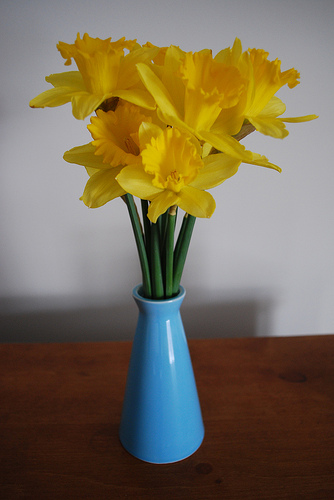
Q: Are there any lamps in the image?
A: No, there are no lamps.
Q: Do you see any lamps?
A: No, there are no lamps.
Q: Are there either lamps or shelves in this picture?
A: No, there are no lamps or shelves.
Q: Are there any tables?
A: Yes, there is a table.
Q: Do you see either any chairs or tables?
A: Yes, there is a table.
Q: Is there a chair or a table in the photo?
A: Yes, there is a table.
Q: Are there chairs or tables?
A: Yes, there is a table.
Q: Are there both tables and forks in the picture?
A: No, there is a table but no forks.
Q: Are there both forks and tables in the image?
A: No, there is a table but no forks.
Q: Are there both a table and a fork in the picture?
A: No, there is a table but no forks.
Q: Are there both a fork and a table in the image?
A: No, there is a table but no forks.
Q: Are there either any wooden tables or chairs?
A: Yes, there is a wood table.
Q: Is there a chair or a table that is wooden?
A: Yes, the table is wooden.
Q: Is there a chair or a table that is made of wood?
A: Yes, the table is made of wood.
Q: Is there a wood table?
A: Yes, there is a table that is made of wood.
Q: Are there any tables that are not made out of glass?
A: Yes, there is a table that is made of wood.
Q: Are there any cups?
A: No, there are no cups.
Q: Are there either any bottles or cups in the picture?
A: No, there are no cups or bottles.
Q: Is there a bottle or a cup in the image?
A: No, there are no cups or bottles.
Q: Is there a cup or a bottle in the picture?
A: No, there are no cups or bottles.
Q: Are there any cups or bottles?
A: No, there are no cups or bottles.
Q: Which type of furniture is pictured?
A: The furniture is a table.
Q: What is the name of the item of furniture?
A: The piece of furniture is a table.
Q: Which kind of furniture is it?
A: The piece of furniture is a table.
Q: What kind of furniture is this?
A: This is a table.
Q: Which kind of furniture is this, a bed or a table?
A: This is a table.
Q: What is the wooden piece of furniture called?
A: The piece of furniture is a table.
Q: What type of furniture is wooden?
A: The furniture is a table.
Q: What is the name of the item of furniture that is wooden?
A: The piece of furniture is a table.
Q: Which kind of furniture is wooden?
A: The furniture is a table.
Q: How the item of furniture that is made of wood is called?
A: The piece of furniture is a table.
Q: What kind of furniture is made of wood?
A: The furniture is a table.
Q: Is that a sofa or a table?
A: That is a table.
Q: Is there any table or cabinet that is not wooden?
A: No, there is a table but it is wooden.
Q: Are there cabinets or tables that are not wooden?
A: No, there is a table but it is wooden.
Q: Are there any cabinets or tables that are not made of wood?
A: No, there is a table but it is made of wood.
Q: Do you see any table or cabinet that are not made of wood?
A: No, there is a table but it is made of wood.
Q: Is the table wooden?
A: Yes, the table is wooden.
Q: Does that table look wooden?
A: Yes, the table is wooden.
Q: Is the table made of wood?
A: Yes, the table is made of wood.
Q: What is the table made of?
A: The table is made of wood.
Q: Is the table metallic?
A: No, the table is wooden.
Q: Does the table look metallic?
A: No, the table is wooden.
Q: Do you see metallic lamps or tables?
A: No, there is a table but it is wooden.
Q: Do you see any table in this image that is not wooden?
A: No, there is a table but it is wooden.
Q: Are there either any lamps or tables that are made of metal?
A: No, there is a table but it is made of wood.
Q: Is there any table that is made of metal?
A: No, there is a table but it is made of wood.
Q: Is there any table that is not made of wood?
A: No, there is a table but it is made of wood.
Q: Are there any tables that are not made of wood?
A: No, there is a table but it is made of wood.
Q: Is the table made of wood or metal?
A: The table is made of wood.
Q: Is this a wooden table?
A: Yes, this is a wooden table.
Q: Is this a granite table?
A: No, this is a wooden table.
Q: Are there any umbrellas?
A: No, there are no umbrellas.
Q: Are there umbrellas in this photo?
A: No, there are no umbrellas.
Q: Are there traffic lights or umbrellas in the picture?
A: No, there are no umbrellas or traffic lights.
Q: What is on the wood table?
A: The vase is on the table.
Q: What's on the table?
A: The vase is on the table.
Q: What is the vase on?
A: The vase is on the table.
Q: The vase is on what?
A: The vase is on the table.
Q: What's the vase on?
A: The vase is on the table.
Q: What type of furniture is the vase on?
A: The vase is on the table.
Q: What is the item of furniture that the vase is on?
A: The piece of furniture is a table.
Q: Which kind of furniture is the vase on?
A: The vase is on the table.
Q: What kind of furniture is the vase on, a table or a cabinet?
A: The vase is on a table.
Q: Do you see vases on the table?
A: Yes, there is a vase on the table.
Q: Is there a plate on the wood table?
A: No, there is a vase on the table.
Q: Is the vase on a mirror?
A: No, the vase is on the table.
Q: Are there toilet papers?
A: No, there are no toilet papers.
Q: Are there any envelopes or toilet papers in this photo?
A: No, there are no toilet papers or envelopes.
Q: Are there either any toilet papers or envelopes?
A: No, there are no toilet papers or envelopes.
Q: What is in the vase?
A: The flowers are in the vase.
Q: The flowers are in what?
A: The flowers are in the vase.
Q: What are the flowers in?
A: The flowers are in the vase.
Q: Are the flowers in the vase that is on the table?
A: Yes, the flowers are in the vase.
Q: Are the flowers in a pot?
A: No, the flowers are in the vase.